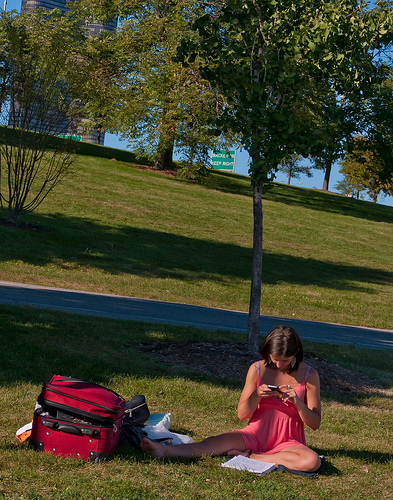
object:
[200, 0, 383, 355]
tree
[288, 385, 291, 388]
ring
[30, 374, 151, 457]
luggage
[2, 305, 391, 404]
shade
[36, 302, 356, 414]
grass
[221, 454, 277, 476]
book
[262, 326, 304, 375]
hair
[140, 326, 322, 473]
lady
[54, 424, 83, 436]
handle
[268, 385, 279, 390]
cell phone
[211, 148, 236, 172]
green sign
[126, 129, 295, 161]
road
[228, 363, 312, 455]
dress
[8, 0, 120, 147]
building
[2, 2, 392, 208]
background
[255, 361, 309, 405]
bra